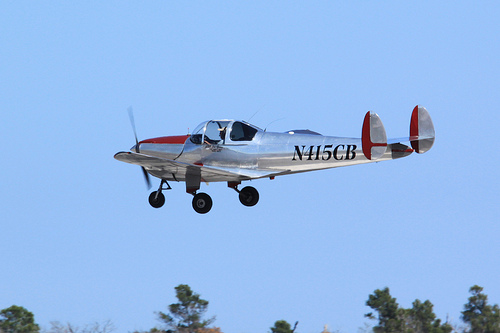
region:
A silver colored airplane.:
[111, 101, 434, 212]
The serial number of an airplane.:
[290, 140, 356, 161]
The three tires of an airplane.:
[146, 186, 259, 213]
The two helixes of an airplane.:
[123, 105, 151, 190]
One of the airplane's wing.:
[112, 149, 289, 179]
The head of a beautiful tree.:
[145, 282, 221, 332]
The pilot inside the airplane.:
[204, 126, 226, 144]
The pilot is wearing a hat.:
[217, 125, 227, 132]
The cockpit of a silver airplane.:
[187, 117, 263, 147]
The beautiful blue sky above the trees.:
[0, 0, 497, 330]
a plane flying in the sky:
[99, 78, 464, 226]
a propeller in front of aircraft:
[102, 89, 157, 196]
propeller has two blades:
[123, 97, 159, 196]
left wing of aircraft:
[101, 142, 209, 183]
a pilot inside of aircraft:
[200, 122, 232, 150]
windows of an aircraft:
[185, 110, 264, 148]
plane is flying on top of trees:
[81, 80, 451, 227]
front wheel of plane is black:
[141, 180, 173, 213]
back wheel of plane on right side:
[230, 183, 265, 212]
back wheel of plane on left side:
[181, 187, 222, 222]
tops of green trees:
[4, 284, 497, 330]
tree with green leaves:
[150, 275, 225, 330]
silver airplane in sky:
[112, 95, 446, 220]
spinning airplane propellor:
[117, 98, 162, 201]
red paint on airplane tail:
[358, 100, 447, 170]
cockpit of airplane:
[184, 113, 266, 145]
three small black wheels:
[143, 172, 260, 217]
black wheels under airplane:
[135, 177, 261, 217]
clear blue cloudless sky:
[112, 8, 423, 86]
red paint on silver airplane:
[134, 125, 194, 155]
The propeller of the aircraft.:
[110, 106, 155, 187]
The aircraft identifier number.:
[287, 143, 370, 165]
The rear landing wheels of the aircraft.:
[181, 184, 263, 213]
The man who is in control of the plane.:
[205, 116, 230, 146]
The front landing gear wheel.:
[146, 183, 166, 207]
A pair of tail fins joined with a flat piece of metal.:
[354, 103, 436, 160]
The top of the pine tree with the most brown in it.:
[153, 277, 220, 332]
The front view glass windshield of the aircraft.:
[189, 111, 206, 144]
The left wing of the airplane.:
[110, 146, 289, 177]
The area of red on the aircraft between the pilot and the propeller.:
[142, 132, 192, 146]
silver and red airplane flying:
[110, 99, 448, 214]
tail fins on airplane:
[355, 102, 438, 172]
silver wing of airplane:
[114, 142, 280, 187]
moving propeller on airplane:
[120, 108, 157, 195]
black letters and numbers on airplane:
[282, 135, 362, 164]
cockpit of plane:
[180, 112, 257, 154]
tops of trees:
[4, 278, 494, 332]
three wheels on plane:
[138, 187, 272, 221]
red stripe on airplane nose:
[127, 135, 190, 145]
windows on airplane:
[187, 115, 256, 141]